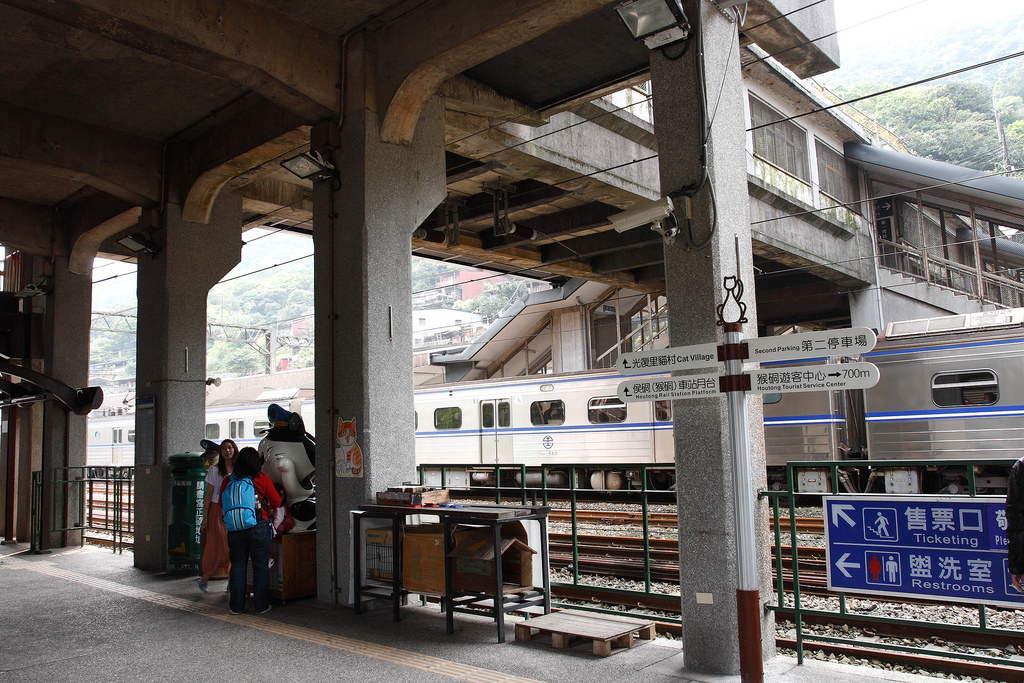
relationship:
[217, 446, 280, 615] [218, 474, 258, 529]
passenger wearing a backpack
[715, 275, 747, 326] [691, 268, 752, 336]
cat that looks like a cat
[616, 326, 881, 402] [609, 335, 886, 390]
asian language written in asian language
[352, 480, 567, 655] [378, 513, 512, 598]
table with bottom shelf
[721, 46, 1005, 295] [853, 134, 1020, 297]
covered walkway over stairway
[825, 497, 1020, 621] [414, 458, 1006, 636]
sign on fence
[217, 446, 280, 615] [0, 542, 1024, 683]
passenger on platform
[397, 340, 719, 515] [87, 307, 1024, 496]
car of car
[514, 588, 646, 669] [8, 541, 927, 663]
wooden palette on platform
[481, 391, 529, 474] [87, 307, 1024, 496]
door of car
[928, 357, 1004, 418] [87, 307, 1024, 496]
window on car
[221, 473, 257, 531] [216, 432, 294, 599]
backpack on passenger